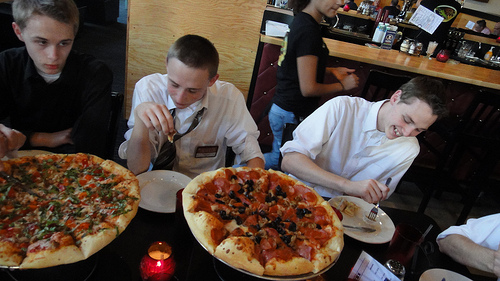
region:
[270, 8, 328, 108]
woman's shirt is black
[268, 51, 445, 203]
man is holding a fork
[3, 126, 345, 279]
pizzas have not been cut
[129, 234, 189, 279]
red candle holder on table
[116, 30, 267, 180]
man is wearing a tie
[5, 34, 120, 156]
man's shirt is black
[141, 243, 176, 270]
candle lit in the holder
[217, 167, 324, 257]
black olives on the pizza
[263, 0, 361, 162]
woman wearing blue jeans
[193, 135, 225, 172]
tag on the man's shirt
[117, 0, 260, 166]
boy sitting in front of wood panel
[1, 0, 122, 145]
boy sitting in front of dark area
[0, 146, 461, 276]
large pizzas on black table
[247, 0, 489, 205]
woman standing in front of counter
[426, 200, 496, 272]
elbow placed on edge of table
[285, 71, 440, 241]
boy leaning over to use fork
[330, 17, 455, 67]
condiments and toothpicks on back of counter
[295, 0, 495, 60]
shelves and person on other side of counter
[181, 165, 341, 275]
puffy crusts on red and black pizza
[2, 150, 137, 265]
whole pie with many toppings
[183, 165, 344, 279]
a pepperoni pizza with black olives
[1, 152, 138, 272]
a vegetarian pizza on a table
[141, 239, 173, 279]
a votive candle in a red glass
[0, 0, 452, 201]
young men sitting at a table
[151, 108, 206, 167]
young man wearing a loose tie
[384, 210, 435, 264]
a glass on a table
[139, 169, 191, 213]
a whit plate on a table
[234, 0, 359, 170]
a woman walking in front of a counter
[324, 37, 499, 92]
a wooden counter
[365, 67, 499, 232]
black stool in front of a counter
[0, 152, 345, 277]
Two pizza pies are on a table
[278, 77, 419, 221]
A boy in a white shirt is holding a fork.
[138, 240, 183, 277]
A candle is burning inside a red cup.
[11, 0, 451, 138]
Three boys with light brown hair.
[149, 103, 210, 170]
A necktie is pulled out and is loose.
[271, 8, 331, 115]
A man is weating a mostly black tee shirt,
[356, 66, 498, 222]
Two black chairs are at a counter.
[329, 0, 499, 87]
A counter has condiments on it.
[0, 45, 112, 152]
A boy is wearing a black shirt.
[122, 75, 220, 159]
A boy is wearing a white shirt with a tag on it.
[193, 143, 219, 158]
A name tag on a shirt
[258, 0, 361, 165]
A lady working her shift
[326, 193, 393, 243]
A guy eating food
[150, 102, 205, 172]
A tie on a shirt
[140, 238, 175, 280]
A candle on a table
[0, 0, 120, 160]
A guy eating pizza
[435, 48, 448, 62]
A red candle on a counter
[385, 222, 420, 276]
A red glass on a table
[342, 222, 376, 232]
A utencil on a plate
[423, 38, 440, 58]
A candle near a bar counter